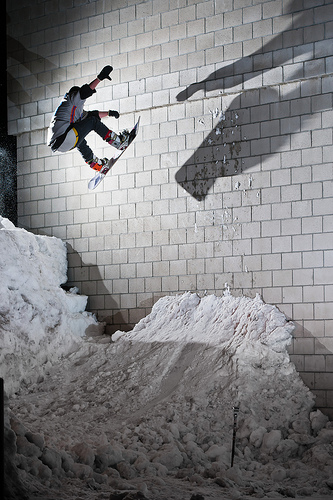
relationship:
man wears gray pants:
[45, 64, 123, 163] [71, 117, 105, 141]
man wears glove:
[45, 64, 123, 163] [97, 63, 117, 81]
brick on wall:
[9, 16, 332, 395] [3, 6, 331, 381]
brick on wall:
[9, 16, 332, 395] [8, 5, 330, 428]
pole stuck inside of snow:
[226, 404, 244, 457] [0, 216, 330, 497]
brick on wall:
[9, 16, 332, 395] [47, 30, 326, 342]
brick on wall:
[88, 267, 103, 281] [8, 5, 330, 428]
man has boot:
[45, 64, 123, 163] [84, 155, 107, 172]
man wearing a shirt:
[45, 64, 123, 163] [51, 98, 81, 136]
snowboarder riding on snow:
[42, 61, 134, 175] [22, 341, 208, 452]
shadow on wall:
[171, 1, 332, 204] [3, 6, 331, 381]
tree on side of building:
[1, 143, 19, 219] [7, 4, 332, 418]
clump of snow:
[93, 440, 125, 467] [0, 216, 330, 497]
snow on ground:
[0, 216, 330, 497] [4, 357, 327, 495]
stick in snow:
[229, 405, 238, 467] [0, 216, 330, 497]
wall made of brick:
[3, 6, 331, 381] [9, 16, 332, 395]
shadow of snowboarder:
[189, 19, 312, 191] [57, 119, 155, 183]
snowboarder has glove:
[42, 61, 134, 175] [97, 63, 117, 81]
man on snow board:
[45, 64, 123, 163] [66, 113, 158, 182]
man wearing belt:
[45, 64, 123, 163] [67, 123, 91, 157]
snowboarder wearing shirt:
[42, 61, 134, 175] [44, 90, 86, 134]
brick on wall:
[9, 16, 332, 395] [63, 0, 319, 307]